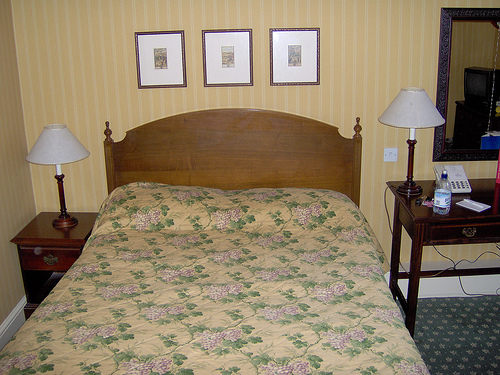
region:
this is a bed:
[29, 114, 392, 371]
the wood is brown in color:
[197, 114, 264, 157]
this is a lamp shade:
[23, 122, 96, 231]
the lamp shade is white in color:
[40, 132, 67, 154]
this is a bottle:
[432, 169, 453, 211]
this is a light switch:
[380, 145, 401, 167]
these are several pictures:
[118, 21, 338, 99]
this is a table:
[388, 180, 482, 300]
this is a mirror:
[456, 23, 498, 88]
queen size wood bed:
[37, 95, 424, 365]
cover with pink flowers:
[66, 171, 376, 373]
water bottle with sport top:
[431, 159, 459, 216]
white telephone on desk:
[432, 161, 471, 195]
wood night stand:
[17, 210, 81, 309]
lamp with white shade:
[22, 112, 85, 229]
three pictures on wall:
[114, 18, 339, 91]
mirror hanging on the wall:
[437, 5, 498, 154]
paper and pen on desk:
[457, 190, 487, 215]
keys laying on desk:
[414, 191, 437, 211]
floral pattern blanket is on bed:
[56, 194, 416, 374]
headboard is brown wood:
[97, 98, 362, 203]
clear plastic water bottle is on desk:
[426, 162, 457, 220]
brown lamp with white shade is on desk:
[375, 83, 452, 208]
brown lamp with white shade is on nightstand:
[14, 117, 99, 237]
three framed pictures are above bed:
[127, 24, 323, 94]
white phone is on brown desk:
[435, 160, 471, 195]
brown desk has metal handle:
[384, 188, 499, 318]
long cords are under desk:
[418, 245, 498, 308]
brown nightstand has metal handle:
[28, 250, 75, 267]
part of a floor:
[441, 323, 461, 354]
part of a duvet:
[199, 336, 255, 371]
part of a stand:
[405, 271, 421, 314]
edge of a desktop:
[29, 238, 53, 251]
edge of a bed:
[387, 298, 409, 340]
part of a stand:
[408, 313, 415, 325]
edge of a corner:
[420, 290, 443, 305]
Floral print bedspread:
[129, 241, 333, 347]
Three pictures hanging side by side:
[116, 16, 346, 101]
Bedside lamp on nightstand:
[20, 116, 93, 285]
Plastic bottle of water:
[429, 171, 456, 219]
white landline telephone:
[434, 157, 482, 197]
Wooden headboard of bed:
[94, 107, 385, 187]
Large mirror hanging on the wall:
[435, 7, 498, 163]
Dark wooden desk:
[384, 171, 499, 324]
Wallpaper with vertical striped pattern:
[28, 23, 133, 113]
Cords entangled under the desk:
[384, 208, 498, 306]